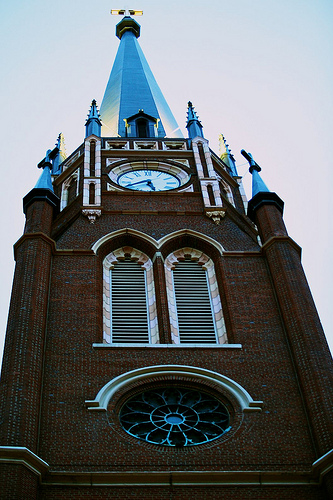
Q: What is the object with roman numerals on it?
A: A clock.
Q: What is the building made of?
A: Brick.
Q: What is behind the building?
A: The sky.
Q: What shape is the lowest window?
A: A circle.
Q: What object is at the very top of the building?
A: A cross.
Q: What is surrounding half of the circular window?
A: An arch.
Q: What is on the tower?
A: Bricks.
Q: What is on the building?
A: Clock.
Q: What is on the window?
A: Slats.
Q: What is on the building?
A: Stone.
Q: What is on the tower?
A: Spire.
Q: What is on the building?
A: Circular window.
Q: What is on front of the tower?
A: Clock.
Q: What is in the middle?
A: A round window.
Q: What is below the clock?
A: Windows.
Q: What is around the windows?
A: Tile.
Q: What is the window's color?
A: Cream.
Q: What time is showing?
A: 5:40.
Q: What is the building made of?
A: Bricks.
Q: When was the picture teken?
A: During the day.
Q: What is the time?
A: 5:40.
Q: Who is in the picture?
A: No one.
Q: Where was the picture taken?
A: By a church.